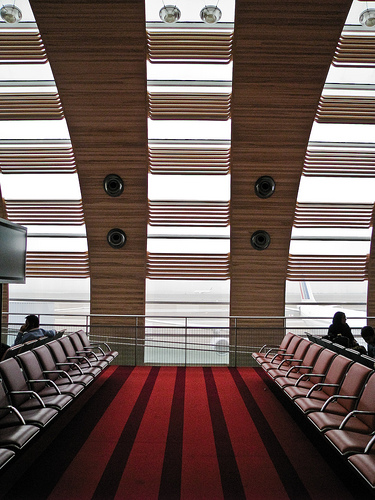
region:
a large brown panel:
[53, 50, 144, 365]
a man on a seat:
[13, 316, 66, 351]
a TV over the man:
[0, 209, 31, 287]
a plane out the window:
[107, 279, 369, 358]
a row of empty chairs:
[241, 319, 372, 434]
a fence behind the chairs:
[8, 309, 347, 369]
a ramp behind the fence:
[72, 326, 288, 366]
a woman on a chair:
[327, 305, 367, 356]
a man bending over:
[351, 326, 371, 351]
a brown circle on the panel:
[107, 226, 125, 248]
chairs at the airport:
[241, 323, 309, 408]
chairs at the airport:
[247, 326, 295, 378]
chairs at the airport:
[56, 328, 124, 374]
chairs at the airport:
[0, 353, 56, 467]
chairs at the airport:
[242, 330, 368, 457]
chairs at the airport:
[15, 346, 95, 412]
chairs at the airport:
[1, 331, 119, 480]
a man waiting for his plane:
[10, 313, 66, 344]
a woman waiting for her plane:
[312, 309, 363, 358]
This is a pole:
[177, 308, 198, 372]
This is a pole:
[227, 310, 245, 370]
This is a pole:
[275, 310, 295, 358]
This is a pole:
[129, 308, 149, 375]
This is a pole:
[81, 309, 92, 347]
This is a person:
[10, 307, 61, 365]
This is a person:
[324, 300, 355, 357]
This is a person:
[356, 316, 373, 363]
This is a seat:
[250, 322, 296, 370]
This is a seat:
[69, 321, 114, 374]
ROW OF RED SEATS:
[257, 336, 373, 498]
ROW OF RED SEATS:
[11, 307, 137, 482]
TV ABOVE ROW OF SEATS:
[0, 205, 29, 277]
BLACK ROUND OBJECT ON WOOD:
[95, 153, 129, 199]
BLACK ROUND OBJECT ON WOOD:
[93, 226, 141, 256]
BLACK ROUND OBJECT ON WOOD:
[245, 213, 284, 245]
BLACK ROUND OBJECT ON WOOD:
[260, 168, 270, 197]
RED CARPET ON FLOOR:
[97, 361, 271, 496]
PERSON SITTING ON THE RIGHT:
[325, 309, 370, 379]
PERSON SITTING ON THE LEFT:
[14, 303, 51, 346]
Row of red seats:
[251, 330, 373, 490]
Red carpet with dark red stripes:
[1, 362, 372, 499]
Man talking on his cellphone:
[1, 313, 65, 358]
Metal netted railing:
[1, 310, 374, 368]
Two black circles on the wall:
[249, 174, 277, 250]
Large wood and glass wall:
[0, 0, 374, 366]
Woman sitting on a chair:
[327, 310, 365, 355]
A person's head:
[361, 323, 373, 349]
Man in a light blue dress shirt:
[0, 314, 65, 364]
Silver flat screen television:
[0, 217, 28, 285]